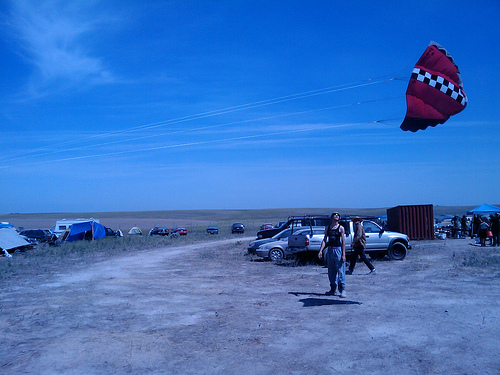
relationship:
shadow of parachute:
[301, 297, 366, 309] [400, 39, 467, 133]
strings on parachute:
[1, 69, 409, 171] [400, 39, 467, 133]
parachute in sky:
[400, 39, 467, 133] [2, 1, 499, 213]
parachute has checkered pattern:
[400, 39, 467, 133] [411, 68, 466, 107]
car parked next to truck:
[254, 232, 294, 263] [286, 217, 413, 263]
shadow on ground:
[301, 297, 366, 309] [0, 206, 499, 374]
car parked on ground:
[254, 232, 294, 263] [0, 206, 499, 374]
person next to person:
[448, 215, 461, 237] [461, 212, 474, 238]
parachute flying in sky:
[400, 39, 467, 133] [2, 1, 499, 213]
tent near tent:
[62, 220, 121, 243] [1, 223, 31, 255]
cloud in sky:
[8, 1, 131, 110] [2, 1, 499, 213]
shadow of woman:
[289, 292, 345, 297] [317, 212, 351, 301]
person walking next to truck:
[344, 215, 378, 276] [286, 217, 413, 263]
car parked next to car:
[254, 232, 294, 263] [246, 225, 325, 261]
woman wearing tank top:
[317, 212, 351, 301] [325, 223, 346, 248]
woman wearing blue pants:
[317, 212, 351, 301] [323, 245, 347, 292]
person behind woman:
[344, 215, 378, 276] [317, 212, 351, 301]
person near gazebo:
[448, 215, 461, 237] [464, 203, 500, 239]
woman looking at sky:
[317, 212, 351, 301] [2, 1, 499, 213]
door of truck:
[351, 220, 389, 250] [286, 217, 413, 263]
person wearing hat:
[344, 215, 378, 276] [350, 215, 366, 224]